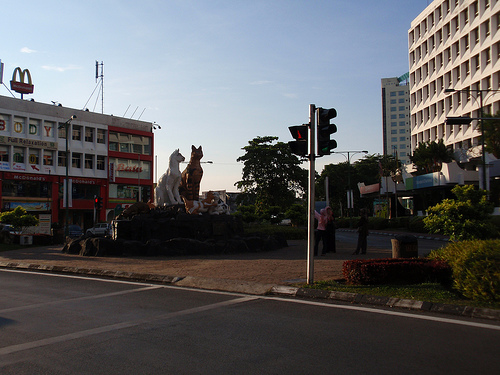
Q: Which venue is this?
A: This is a street.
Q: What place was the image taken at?
A: It was taken at the street.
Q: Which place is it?
A: It is a street.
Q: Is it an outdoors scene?
A: Yes, it is outdoors.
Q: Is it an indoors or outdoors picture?
A: It is outdoors.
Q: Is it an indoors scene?
A: No, it is outdoors.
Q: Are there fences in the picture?
A: No, there are no fences.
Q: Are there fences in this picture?
A: No, there are no fences.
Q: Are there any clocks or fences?
A: No, there are no fences or clocks.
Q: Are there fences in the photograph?
A: No, there are no fences.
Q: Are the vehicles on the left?
A: Yes, the vehicles are on the left of the image.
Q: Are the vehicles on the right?
A: No, the vehicles are on the left of the image.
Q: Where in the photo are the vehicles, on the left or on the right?
A: The vehicles are on the left of the image.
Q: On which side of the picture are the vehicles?
A: The vehicles are on the left of the image.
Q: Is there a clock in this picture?
A: No, there are no clocks.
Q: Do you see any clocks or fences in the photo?
A: No, there are no clocks or fences.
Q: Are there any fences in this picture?
A: No, there are no fences.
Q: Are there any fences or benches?
A: No, there are no fences or benches.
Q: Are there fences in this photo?
A: No, there are no fences.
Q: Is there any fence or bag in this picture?
A: No, there are no fences or bags.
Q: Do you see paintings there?
A: No, there are no paintings.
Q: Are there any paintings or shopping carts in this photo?
A: No, there are no paintings or shopping carts.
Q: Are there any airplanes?
A: No, there are no airplanes.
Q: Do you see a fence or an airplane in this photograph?
A: No, there are no airplanes or fences.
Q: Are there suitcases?
A: No, there are no suitcases.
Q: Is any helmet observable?
A: No, there are no helmets.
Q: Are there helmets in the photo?
A: No, there are no helmets.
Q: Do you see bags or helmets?
A: No, there are no helmets or bags.